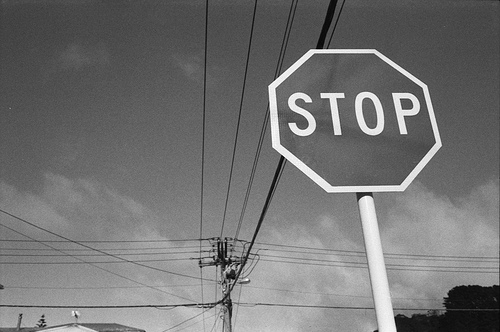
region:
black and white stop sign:
[247, 38, 453, 208]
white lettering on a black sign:
[286, 90, 420, 144]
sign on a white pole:
[354, 190, 397, 330]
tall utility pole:
[198, 234, 246, 330]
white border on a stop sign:
[266, 43, 444, 193]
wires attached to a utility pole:
[1, 3, 496, 330]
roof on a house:
[0, 321, 148, 330]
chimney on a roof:
[12, 309, 26, 327]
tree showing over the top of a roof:
[30, 312, 47, 329]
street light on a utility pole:
[226, 277, 252, 287]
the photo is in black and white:
[42, 28, 338, 267]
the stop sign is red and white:
[252, 30, 486, 323]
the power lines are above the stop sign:
[162, 64, 407, 316]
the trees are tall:
[385, 239, 467, 314]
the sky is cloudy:
[47, 87, 167, 282]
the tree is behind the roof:
[17, 309, 68, 327]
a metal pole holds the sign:
[328, 177, 440, 317]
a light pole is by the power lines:
[182, 222, 275, 327]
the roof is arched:
[38, 316, 118, 329]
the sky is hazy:
[95, 79, 335, 309]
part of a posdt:
[366, 236, 380, 267]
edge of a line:
[341, 171, 356, 197]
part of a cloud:
[320, 261, 332, 283]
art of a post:
[368, 233, 400, 276]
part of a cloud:
[286, 275, 303, 315]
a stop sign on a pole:
[258, 42, 450, 213]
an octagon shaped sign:
[260, 42, 475, 224]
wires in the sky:
[18, 207, 499, 312]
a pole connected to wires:
[178, 212, 271, 329]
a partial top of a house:
[5, 307, 157, 330]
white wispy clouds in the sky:
[28, 148, 489, 305]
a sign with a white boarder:
[257, 32, 444, 197]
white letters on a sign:
[275, 72, 428, 157]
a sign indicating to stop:
[262, 32, 443, 225]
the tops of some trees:
[389, 282, 499, 330]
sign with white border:
[261, 36, 443, 193]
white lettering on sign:
[284, 83, 416, 139]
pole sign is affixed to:
[358, 194, 395, 330]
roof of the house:
[8, 309, 151, 330]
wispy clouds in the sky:
[8, 160, 498, 327]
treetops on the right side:
[379, 267, 498, 330]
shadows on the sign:
[290, 48, 390, 148]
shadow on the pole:
[356, 192, 376, 209]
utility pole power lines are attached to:
[198, 241, 244, 330]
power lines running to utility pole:
[9, 23, 449, 330]